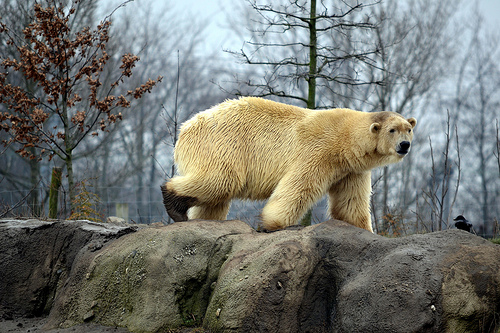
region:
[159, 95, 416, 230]
White polar bear with black nose.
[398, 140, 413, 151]
Black nose on a white polar bear.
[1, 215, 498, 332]
Grey large rock a polar bear is on going from left to right.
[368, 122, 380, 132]
A polar bears right ear.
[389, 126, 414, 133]
Black eyes of a white polar bear.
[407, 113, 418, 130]
A polar bears left ear.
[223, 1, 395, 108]
Thin branch tree with no leaves sticking up behind a polar bear.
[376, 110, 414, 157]
The white and black head of a polar bear.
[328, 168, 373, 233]
A polar bears left front arm.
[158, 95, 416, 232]
A white polar bear walking.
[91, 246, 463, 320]
The rocks on the ground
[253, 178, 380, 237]
The legs of the polar bear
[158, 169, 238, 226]
The back legs of the polar bear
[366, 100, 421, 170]
The head of the polar bear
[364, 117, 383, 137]
The ear of the bear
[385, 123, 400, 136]
The eye of the bear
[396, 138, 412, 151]
The nose of the bear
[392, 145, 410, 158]
The mouth of the bear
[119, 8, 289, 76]
The sky is the color gray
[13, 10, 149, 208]
The tree is small with brown leaves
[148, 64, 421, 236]
A large light brown bear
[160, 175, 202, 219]
A brown bear with black paw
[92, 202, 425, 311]
A large rock or bolder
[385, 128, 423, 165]
A black nose on brown bear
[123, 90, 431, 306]
A brown bear walking on a large rock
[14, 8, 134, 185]
A small tree with brown leaves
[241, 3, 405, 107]
A leafless tree behind bear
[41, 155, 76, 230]
A wooden post behind rock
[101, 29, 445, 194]
A forest behind bear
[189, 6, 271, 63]
Blue sky behind trees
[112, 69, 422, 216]
large white polar bear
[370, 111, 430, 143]
bear has white ears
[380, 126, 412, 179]
bear has dark nose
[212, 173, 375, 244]
bear has white legs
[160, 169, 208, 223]
bear has dark brown paws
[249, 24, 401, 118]
bare tree behind bear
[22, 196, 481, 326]
bear on grey rocks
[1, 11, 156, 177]
brown leaves on tree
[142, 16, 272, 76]
sky is grey and cloudy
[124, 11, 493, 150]
large trees in background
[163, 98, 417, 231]
white and tan bear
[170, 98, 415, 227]
polar bear on boulder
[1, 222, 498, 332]
grey rock barrier wall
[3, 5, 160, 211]
tree with brown leaves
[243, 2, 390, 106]
tree with no leaves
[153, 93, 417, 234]
bear standing on boulder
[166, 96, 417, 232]
bear walking on boulder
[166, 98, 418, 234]
bear walking on rock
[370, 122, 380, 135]
white ear on bear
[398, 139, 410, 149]
black nose on bear